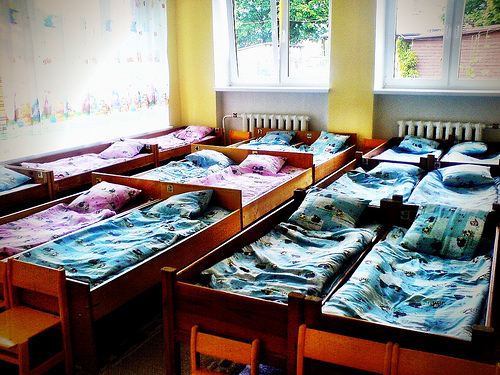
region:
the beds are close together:
[21, 110, 478, 351]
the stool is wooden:
[183, 329, 270, 371]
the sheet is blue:
[71, 213, 197, 266]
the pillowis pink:
[238, 145, 285, 168]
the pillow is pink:
[100, 138, 135, 155]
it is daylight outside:
[242, 8, 326, 103]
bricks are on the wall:
[414, 40, 499, 74]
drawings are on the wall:
[11, 20, 167, 128]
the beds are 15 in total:
[0, 112, 477, 349]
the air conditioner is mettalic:
[402, 114, 482, 145]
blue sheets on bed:
[337, 208, 469, 327]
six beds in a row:
[232, 138, 495, 336]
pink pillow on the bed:
[236, 155, 276, 169]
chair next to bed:
[0, 274, 75, 364]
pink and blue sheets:
[176, 154, 278, 182]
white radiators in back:
[228, 115, 307, 125]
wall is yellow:
[320, 4, 375, 138]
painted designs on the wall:
[15, 95, 170, 130]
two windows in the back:
[380, 5, 496, 81]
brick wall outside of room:
[377, 42, 497, 80]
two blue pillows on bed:
[291, 186, 475, 257]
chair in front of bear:
[176, 325, 267, 371]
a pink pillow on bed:
[78, 177, 128, 209]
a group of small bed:
[5, 119, 489, 367]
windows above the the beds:
[230, 7, 334, 91]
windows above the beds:
[388, 3, 493, 93]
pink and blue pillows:
[189, 145, 293, 174]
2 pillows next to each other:
[290, 180, 482, 260]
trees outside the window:
[234, 0, 333, 40]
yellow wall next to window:
[171, 3, 214, 125]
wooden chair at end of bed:
[0, 259, 70, 370]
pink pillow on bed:
[234, 153, 289, 175]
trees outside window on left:
[233, 3, 330, 46]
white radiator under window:
[220, 111, 317, 135]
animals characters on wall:
[0, 79, 172, 133]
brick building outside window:
[393, 23, 496, 85]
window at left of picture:
[219, 1, 338, 93]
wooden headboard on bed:
[164, 185, 243, 209]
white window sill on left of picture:
[219, 85, 331, 95]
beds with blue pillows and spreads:
[179, 140, 498, 349]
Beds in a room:
[175, 163, 346, 249]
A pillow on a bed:
[313, 197, 345, 224]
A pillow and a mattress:
[303, 213, 330, 253]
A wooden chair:
[6, 313, 33, 331]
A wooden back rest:
[320, 343, 370, 358]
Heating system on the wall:
[408, 125, 458, 135]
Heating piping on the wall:
[226, 114, 237, 118]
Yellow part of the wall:
[341, 96, 363, 130]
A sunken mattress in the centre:
[396, 270, 429, 307]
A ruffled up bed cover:
[263, 260, 298, 279]